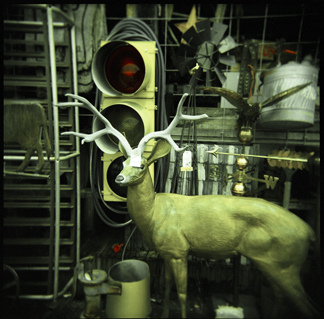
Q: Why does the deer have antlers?
A: It is male.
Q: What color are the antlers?
A: White.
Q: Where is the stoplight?
A: Behind the deer.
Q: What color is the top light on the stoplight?
A: Red.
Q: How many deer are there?
A: One.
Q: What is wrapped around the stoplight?
A: A cord.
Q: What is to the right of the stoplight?
A: A windmill.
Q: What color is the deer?
A: Tan.